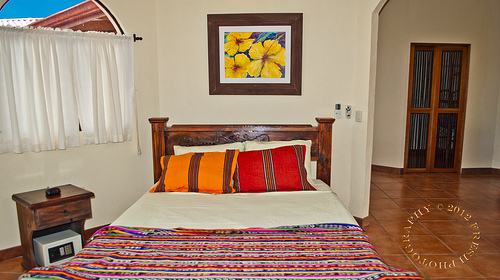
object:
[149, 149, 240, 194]
pillow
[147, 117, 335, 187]
plate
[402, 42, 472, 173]
door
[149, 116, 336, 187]
headboard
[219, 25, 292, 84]
picture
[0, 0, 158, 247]
wall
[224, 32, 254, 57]
flower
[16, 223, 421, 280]
blanket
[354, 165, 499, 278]
tile floor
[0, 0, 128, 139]
window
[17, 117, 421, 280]
bed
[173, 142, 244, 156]
pillow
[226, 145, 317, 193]
pillow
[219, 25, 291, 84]
painting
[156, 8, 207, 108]
wall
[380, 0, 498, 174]
wall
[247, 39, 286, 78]
flower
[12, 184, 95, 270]
nightstand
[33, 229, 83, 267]
safe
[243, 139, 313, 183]
pillow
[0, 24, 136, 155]
curtain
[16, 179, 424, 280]
bed spread